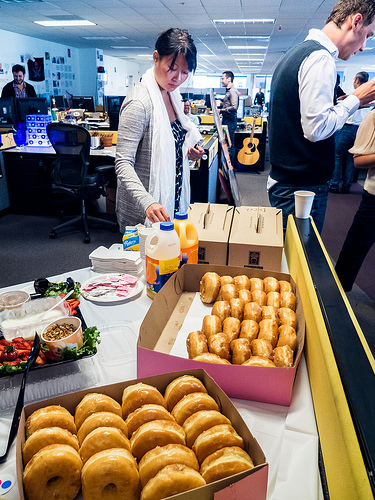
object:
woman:
[112, 26, 207, 235]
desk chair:
[44, 120, 114, 246]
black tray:
[0, 275, 98, 379]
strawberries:
[0, 344, 19, 362]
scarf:
[140, 63, 204, 227]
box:
[13, 367, 270, 499]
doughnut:
[22, 440, 87, 498]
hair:
[154, 26, 199, 76]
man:
[265, 0, 374, 243]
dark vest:
[267, 36, 341, 192]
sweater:
[113, 78, 158, 236]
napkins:
[88, 243, 143, 263]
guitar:
[236, 118, 259, 167]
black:
[39, 279, 45, 292]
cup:
[292, 189, 318, 220]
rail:
[283, 210, 374, 500]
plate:
[79, 269, 145, 304]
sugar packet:
[119, 273, 141, 284]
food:
[41, 320, 78, 342]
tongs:
[0, 329, 42, 465]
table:
[0, 245, 327, 498]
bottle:
[142, 218, 179, 300]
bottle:
[170, 211, 198, 266]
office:
[0, 0, 375, 499]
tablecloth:
[0, 246, 331, 498]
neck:
[151, 63, 167, 96]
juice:
[144, 228, 181, 303]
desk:
[233, 119, 267, 175]